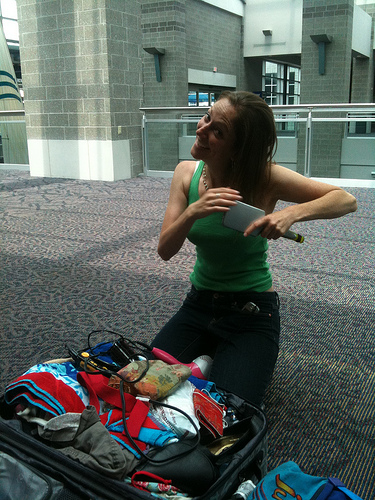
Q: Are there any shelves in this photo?
A: No, there are no shelves.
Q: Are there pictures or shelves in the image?
A: No, there are no shelves or pictures.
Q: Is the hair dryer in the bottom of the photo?
A: Yes, the hair dryer is in the bottom of the image.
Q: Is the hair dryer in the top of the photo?
A: No, the hair dryer is in the bottom of the image.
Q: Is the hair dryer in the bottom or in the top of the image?
A: The hair dryer is in the bottom of the image.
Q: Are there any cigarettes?
A: No, there are no cigarettes.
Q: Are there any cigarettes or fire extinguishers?
A: No, there are no cigarettes or fire extinguishers.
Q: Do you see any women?
A: Yes, there is a woman.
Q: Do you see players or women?
A: Yes, there is a woman.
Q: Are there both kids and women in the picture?
A: No, there is a woman but no children.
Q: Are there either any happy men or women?
A: Yes, there is a happy woman.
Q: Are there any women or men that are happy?
A: Yes, the woman is happy.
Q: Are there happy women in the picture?
A: Yes, there is a happy woman.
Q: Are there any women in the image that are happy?
A: Yes, there is a woman that is happy.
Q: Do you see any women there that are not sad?
A: Yes, there is a happy woman.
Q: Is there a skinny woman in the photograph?
A: Yes, there is a skinny woman.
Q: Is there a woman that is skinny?
A: Yes, there is a woman that is skinny.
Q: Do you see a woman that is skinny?
A: Yes, there is a woman that is skinny.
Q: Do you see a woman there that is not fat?
A: Yes, there is a skinny woman.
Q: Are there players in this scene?
A: No, there are no players.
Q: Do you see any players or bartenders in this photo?
A: No, there are no players or bartenders.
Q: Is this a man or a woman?
A: This is a woman.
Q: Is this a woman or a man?
A: This is a woman.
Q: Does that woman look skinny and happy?
A: Yes, the woman is skinny and happy.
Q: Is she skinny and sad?
A: No, the woman is skinny but happy.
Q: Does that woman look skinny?
A: Yes, the woman is skinny.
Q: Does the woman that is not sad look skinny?
A: Yes, the woman is skinny.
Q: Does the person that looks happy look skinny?
A: Yes, the woman is skinny.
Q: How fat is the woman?
A: The woman is skinny.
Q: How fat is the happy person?
A: The woman is skinny.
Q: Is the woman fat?
A: No, the woman is skinny.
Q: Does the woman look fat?
A: No, the woman is skinny.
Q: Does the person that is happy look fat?
A: No, the woman is skinny.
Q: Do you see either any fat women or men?
A: No, there is a woman but she is skinny.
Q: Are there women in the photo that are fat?
A: No, there is a woman but she is skinny.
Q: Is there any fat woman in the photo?
A: No, there is a woman but she is skinny.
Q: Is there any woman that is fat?
A: No, there is a woman but she is skinny.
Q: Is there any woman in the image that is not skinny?
A: No, there is a woman but she is skinny.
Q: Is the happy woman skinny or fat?
A: The woman is skinny.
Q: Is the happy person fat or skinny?
A: The woman is skinny.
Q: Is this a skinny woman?
A: Yes, this is a skinny woman.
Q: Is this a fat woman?
A: No, this is a skinny woman.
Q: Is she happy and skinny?
A: Yes, the woman is happy and skinny.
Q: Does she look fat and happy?
A: No, the woman is happy but skinny.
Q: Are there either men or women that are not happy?
A: No, there is a woman but she is happy.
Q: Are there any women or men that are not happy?
A: No, there is a woman but she is happy.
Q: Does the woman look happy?
A: Yes, the woman is happy.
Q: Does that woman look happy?
A: Yes, the woman is happy.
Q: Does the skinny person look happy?
A: Yes, the woman is happy.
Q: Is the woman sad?
A: No, the woman is happy.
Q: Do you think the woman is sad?
A: No, the woman is happy.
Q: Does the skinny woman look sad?
A: No, the woman is happy.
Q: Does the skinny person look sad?
A: No, the woman is happy.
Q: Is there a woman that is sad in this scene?
A: No, there is a woman but she is happy.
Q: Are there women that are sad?
A: No, there is a woman but she is happy.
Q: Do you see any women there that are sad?
A: No, there is a woman but she is happy.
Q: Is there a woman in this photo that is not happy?
A: No, there is a woman but she is happy.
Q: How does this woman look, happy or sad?
A: The woman is happy.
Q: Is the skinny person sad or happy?
A: The woman is happy.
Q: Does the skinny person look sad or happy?
A: The woman is happy.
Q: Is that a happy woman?
A: Yes, that is a happy woman.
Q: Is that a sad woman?
A: No, that is a happy woman.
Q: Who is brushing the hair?
A: The woman is brushing the hair.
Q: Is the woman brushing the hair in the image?
A: Yes, the woman is brushing the hair.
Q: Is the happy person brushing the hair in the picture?
A: Yes, the woman is brushing the hair.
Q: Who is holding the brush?
A: The woman is holding the brush.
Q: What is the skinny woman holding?
A: The woman is holding the brush.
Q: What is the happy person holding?
A: The woman is holding the brush.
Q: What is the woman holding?
A: The woman is holding the brush.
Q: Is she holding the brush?
A: Yes, the woman is holding the brush.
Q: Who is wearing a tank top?
A: The woman is wearing a tank top.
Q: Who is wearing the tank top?
A: The woman is wearing a tank top.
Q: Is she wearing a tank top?
A: Yes, the woman is wearing a tank top.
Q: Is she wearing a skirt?
A: No, the woman is wearing a tank top.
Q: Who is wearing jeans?
A: The woman is wearing jeans.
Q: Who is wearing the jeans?
A: The woman is wearing jeans.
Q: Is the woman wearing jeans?
A: Yes, the woman is wearing jeans.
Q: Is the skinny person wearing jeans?
A: Yes, the woman is wearing jeans.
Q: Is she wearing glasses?
A: No, the woman is wearing jeans.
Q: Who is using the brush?
A: The woman is using the brush.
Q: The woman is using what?
A: The woman is using a brush.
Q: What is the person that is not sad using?
A: The woman is using a brush.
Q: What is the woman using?
A: The woman is using a brush.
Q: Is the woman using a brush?
A: Yes, the woman is using a brush.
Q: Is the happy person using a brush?
A: Yes, the woman is using a brush.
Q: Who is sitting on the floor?
A: The woman is sitting on the floor.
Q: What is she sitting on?
A: The woman is sitting on the floor.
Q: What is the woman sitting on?
A: The woman is sitting on the floor.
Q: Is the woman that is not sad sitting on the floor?
A: Yes, the woman is sitting on the floor.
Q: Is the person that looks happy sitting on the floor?
A: Yes, the woman is sitting on the floor.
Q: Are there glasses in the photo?
A: No, there are no glasses.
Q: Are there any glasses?
A: No, there are no glasses.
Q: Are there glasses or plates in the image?
A: No, there are no glasses or plates.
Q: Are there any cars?
A: No, there are no cars.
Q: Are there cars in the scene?
A: No, there are no cars.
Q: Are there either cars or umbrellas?
A: No, there are no cars or umbrellas.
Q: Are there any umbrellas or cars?
A: No, there are no cars or umbrellas.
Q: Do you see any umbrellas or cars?
A: No, there are no cars or umbrellas.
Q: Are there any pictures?
A: No, there are no pictures.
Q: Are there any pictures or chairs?
A: No, there are no pictures or chairs.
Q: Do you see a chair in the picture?
A: No, there are no chairs.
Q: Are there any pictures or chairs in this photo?
A: No, there are no chairs or pictures.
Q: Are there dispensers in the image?
A: No, there are no dispensers.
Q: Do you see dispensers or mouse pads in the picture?
A: No, there are no dispensers or mouse pads.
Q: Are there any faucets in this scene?
A: No, there are no faucets.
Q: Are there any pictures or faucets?
A: No, there are no faucets or pictures.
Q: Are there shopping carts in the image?
A: No, there are no shopping carts.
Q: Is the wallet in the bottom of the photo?
A: Yes, the wallet is in the bottom of the image.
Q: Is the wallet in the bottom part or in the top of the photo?
A: The wallet is in the bottom of the image.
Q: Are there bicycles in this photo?
A: No, there are no bicycles.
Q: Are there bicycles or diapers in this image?
A: No, there are no bicycles or diapers.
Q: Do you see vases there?
A: No, there are no vases.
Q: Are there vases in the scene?
A: No, there are no vases.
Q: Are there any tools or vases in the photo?
A: No, there are no vases or tools.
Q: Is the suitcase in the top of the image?
A: No, the suitcase is in the bottom of the image.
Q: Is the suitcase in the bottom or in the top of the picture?
A: The suitcase is in the bottom of the image.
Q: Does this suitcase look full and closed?
A: No, the suitcase is full but open.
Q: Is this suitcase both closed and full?
A: No, the suitcase is full but open.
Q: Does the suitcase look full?
A: Yes, the suitcase is full.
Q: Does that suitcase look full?
A: Yes, the suitcase is full.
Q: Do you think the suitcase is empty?
A: No, the suitcase is full.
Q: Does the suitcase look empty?
A: No, the suitcase is full.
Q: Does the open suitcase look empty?
A: No, the suitcase is full.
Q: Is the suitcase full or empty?
A: The suitcase is full.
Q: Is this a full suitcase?
A: Yes, this is a full suitcase.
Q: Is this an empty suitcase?
A: No, this is a full suitcase.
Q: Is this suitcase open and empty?
A: No, the suitcase is open but full.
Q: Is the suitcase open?
A: Yes, the suitcase is open.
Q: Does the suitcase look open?
A: Yes, the suitcase is open.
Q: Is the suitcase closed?
A: No, the suitcase is open.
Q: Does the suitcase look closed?
A: No, the suitcase is open.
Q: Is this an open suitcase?
A: Yes, this is an open suitcase.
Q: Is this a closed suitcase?
A: No, this is an open suitcase.